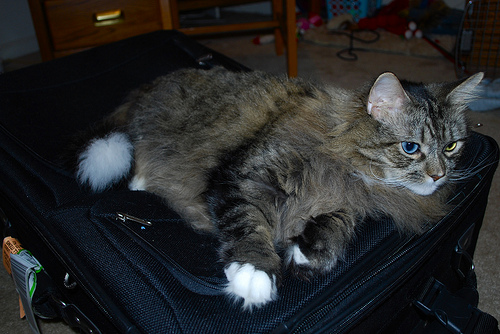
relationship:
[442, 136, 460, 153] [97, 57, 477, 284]
eye reflecting cat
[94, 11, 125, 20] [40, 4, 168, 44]
brass handle on drawer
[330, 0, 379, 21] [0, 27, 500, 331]
crate on ground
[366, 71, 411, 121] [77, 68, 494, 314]
ear belonging to cat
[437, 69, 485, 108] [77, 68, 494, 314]
ear belonging to cat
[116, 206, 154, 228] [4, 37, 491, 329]
clasp attached to suitcase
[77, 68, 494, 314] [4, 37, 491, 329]
cat lying on suitcase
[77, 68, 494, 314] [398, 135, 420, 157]
cat has eye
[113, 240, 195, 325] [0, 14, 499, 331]
suitcase on ground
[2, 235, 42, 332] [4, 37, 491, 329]
label on suitcase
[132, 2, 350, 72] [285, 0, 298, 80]
desk has leg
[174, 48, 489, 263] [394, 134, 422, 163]
cat has eye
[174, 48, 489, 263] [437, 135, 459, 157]
cat has eye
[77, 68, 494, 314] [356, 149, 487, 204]
cat has whiskers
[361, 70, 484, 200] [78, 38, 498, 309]
head on cat